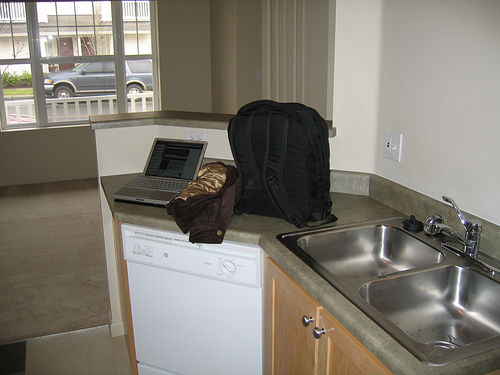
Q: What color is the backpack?
A: Black.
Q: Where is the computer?
A: On the counter.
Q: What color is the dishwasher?
A: White.